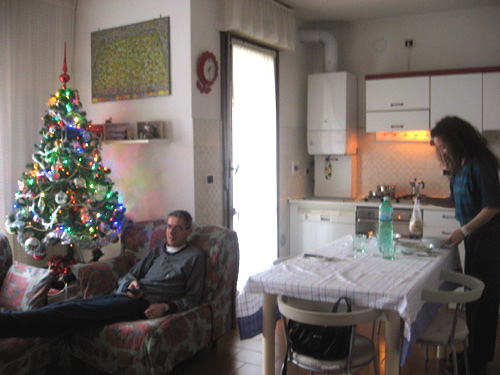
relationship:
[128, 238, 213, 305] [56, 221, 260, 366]
man in chair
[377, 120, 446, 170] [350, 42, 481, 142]
light under cabinet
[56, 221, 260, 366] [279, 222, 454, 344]
chair under table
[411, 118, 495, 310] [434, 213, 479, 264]
woman has hand